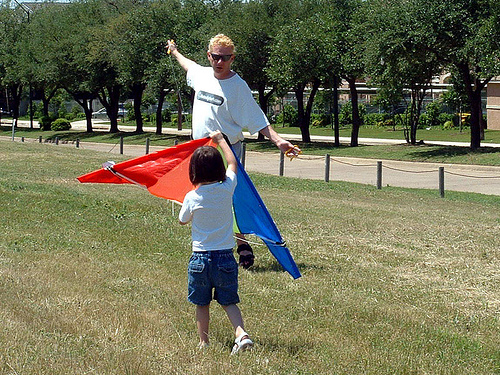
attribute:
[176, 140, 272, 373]
girl — young, foot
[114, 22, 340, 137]
man — wearing, flying, looking, holding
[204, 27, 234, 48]
hair — curly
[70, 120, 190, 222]
kite — red, string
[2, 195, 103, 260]
grass — green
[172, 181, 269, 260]
shirt — white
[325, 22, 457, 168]
tree — leave, many, row, lined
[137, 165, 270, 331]
child — holding, wearing, small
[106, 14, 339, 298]
people — standing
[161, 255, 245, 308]
short — denim